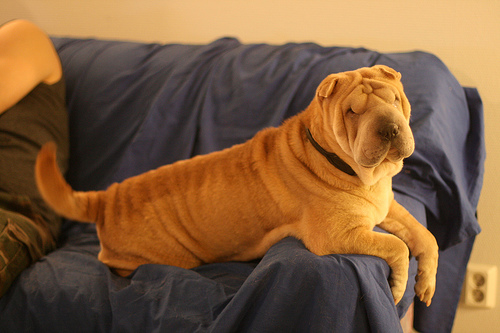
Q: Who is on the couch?
A: The dog.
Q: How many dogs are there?
A: One.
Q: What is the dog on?
A: A couch.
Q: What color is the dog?
A: Blonde.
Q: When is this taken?
A: During the day.